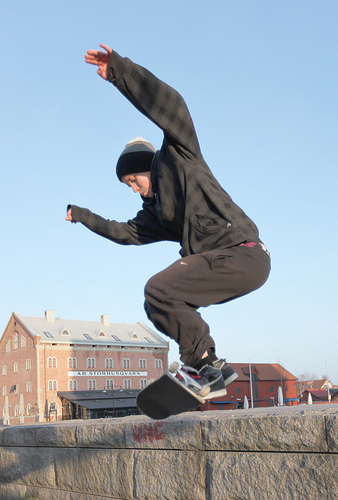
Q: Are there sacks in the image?
A: No, there are no sacks.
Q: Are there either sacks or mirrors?
A: No, there are no sacks or mirrors.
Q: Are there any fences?
A: Yes, there is a fence.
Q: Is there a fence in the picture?
A: Yes, there is a fence.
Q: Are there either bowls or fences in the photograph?
A: Yes, there is a fence.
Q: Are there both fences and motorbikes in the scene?
A: No, there is a fence but no motorcycles.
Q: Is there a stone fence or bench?
A: Yes, there is a stone fence.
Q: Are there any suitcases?
A: No, there are no suitcases.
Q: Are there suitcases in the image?
A: No, there are no suitcases.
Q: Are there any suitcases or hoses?
A: No, there are no suitcases or hoses.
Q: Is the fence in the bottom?
A: Yes, the fence is in the bottom of the image.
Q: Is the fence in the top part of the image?
A: No, the fence is in the bottom of the image.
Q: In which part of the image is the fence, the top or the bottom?
A: The fence is in the bottom of the image.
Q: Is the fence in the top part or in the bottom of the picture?
A: The fence is in the bottom of the image.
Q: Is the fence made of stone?
A: Yes, the fence is made of stone.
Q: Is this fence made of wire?
A: No, the fence is made of stone.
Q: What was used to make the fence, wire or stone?
A: The fence is made of stone.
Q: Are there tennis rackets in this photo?
A: No, there are no tennis rackets.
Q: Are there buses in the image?
A: No, there are no buses.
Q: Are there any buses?
A: No, there are no buses.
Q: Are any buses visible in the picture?
A: No, there are no buses.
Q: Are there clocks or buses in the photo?
A: No, there are no buses or clocks.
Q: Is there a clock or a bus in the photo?
A: No, there are no buses or clocks.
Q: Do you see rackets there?
A: No, there are no rackets.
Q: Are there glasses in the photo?
A: No, there are no glasses.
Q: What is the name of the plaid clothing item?
A: The clothing item is a shirt.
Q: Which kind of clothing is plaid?
A: The clothing is a shirt.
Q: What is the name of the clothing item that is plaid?
A: The clothing item is a shirt.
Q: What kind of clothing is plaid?
A: The clothing is a shirt.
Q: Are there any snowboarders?
A: No, there are no snowboarders.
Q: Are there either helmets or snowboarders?
A: No, there are no snowboarders or helmets.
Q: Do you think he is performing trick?
A: Yes, the boy is performing trick.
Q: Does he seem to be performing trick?
A: Yes, the boy is performing trick.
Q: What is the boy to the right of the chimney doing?
A: The boy is performing trick.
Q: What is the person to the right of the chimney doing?
A: The boy is performing trick.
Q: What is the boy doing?
A: The boy is performing trick.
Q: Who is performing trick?
A: The boy is performing trick.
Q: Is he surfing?
A: No, the boy is performing trick.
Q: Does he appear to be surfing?
A: No, the boy is performing trick.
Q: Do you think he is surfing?
A: No, the boy is performing trick.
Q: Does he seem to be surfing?
A: No, the boy is performing trick.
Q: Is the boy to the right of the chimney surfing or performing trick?
A: The boy is performing trick.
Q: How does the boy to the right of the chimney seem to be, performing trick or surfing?
A: The boy is performing trick.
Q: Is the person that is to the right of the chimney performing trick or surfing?
A: The boy is performing trick.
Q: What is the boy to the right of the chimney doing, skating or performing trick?
A: The boy is performing trick.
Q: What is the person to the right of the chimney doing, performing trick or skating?
A: The boy is performing trick.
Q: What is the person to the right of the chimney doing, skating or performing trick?
A: The boy is performing trick.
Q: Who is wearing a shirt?
A: The boy is wearing a shirt.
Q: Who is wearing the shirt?
A: The boy is wearing a shirt.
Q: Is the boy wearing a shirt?
A: Yes, the boy is wearing a shirt.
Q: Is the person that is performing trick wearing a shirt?
A: Yes, the boy is wearing a shirt.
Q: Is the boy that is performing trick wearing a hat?
A: No, the boy is wearing a shirt.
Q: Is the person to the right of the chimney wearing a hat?
A: No, the boy is wearing a shirt.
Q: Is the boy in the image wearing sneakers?
A: Yes, the boy is wearing sneakers.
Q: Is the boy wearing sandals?
A: No, the boy is wearing sneakers.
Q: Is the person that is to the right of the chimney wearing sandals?
A: No, the boy is wearing sneakers.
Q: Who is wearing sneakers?
A: The boy is wearing sneakers.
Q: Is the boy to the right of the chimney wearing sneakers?
A: Yes, the boy is wearing sneakers.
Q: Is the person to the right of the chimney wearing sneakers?
A: Yes, the boy is wearing sneakers.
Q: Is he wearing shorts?
A: No, the boy is wearing sneakers.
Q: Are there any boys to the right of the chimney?
A: Yes, there is a boy to the right of the chimney.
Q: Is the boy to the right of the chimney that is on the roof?
A: Yes, the boy is to the right of the chimney.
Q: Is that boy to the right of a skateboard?
A: No, the boy is to the right of the chimney.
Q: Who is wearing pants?
A: The boy is wearing pants.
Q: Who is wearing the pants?
A: The boy is wearing pants.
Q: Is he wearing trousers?
A: Yes, the boy is wearing trousers.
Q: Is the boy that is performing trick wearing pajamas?
A: No, the boy is wearing trousers.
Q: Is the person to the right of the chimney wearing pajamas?
A: No, the boy is wearing trousers.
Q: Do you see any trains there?
A: No, there are no trains.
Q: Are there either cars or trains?
A: No, there are no trains or cars.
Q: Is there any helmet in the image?
A: No, there are no helmets.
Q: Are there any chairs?
A: No, there are no chairs.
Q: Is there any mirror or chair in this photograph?
A: No, there are no chairs or mirrors.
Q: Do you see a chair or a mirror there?
A: No, there are no chairs or mirrors.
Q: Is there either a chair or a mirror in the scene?
A: No, there are no chairs or mirrors.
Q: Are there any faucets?
A: No, there are no faucets.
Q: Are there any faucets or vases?
A: No, there are no faucets or vases.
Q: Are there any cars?
A: No, there are no cars.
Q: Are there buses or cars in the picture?
A: No, there are no cars or buses.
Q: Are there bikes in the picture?
A: No, there are no bikes.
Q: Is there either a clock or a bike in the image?
A: No, there are no bikes or clocks.